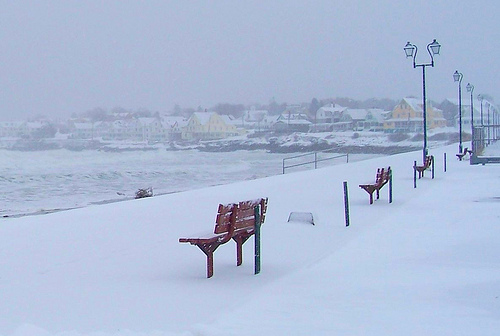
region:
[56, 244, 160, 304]
White snow on the ground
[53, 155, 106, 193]
Water near the benches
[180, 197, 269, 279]
A bench with snow on it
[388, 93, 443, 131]
A house under the snowy sky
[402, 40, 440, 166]
A lampost above the snow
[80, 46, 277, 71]
A snowy sky above the water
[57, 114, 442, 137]
Buildings far from the benches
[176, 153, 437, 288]
Benches on the snow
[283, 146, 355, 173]
A railing near the water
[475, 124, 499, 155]
A fence by the benches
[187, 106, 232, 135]
house is yellow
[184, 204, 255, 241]
bench is red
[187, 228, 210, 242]
snow on the bench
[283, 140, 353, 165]
railing down to the water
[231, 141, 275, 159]
rocks along the water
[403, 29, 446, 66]
two lights on light pole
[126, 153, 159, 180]
waves in the water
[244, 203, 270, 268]
pole behind the bench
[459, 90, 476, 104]
snow on the roof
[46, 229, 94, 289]
snow on the walkway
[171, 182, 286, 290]
This is a beach seat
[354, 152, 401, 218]
This is a beach seat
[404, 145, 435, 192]
This is a beach seat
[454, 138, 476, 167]
This is a beach seat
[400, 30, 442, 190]
This is a lamp pole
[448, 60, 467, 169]
This is a lamp pole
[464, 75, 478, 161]
This is a lamp pole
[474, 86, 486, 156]
This is a lamp pole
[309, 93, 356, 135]
This is a building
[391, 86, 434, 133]
This is a building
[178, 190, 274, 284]
Red bench with a green pole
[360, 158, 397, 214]
Red bench with a green pole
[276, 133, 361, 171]
Fencing along the edge of the water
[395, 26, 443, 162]
Lamp post with two lights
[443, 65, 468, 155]
Tall dark lamp post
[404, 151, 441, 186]
Red bench with two green poles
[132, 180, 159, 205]
Object by the edge of the water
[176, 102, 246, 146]
Yellow building in the background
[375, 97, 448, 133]
Orange building in the background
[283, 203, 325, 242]
Object buried in the snow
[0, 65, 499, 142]
collection of houses covered in snow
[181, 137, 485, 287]
several benches covered in the snow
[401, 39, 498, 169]
group of lights over the benches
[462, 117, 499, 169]
fence enclosing the field behind the benches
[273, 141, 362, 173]
hand rail leading down to the water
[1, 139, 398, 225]
ocean on a snowy day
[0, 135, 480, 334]
walkway and benches covered in snow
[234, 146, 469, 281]
line of green posts behind the benches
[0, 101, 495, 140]
neighborhood next to the ocean covered in snow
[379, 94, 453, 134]
large yellow house in the snow